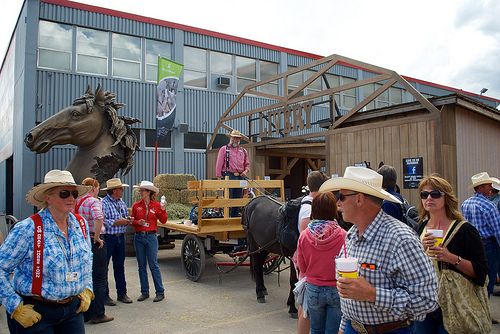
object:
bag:
[436, 219, 492, 334]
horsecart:
[126, 173, 309, 318]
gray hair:
[228, 137, 241, 147]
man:
[460, 171, 500, 299]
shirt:
[215, 142, 250, 176]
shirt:
[72, 193, 108, 234]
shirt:
[0, 207, 93, 315]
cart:
[131, 173, 285, 282]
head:
[335, 189, 381, 223]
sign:
[402, 156, 423, 189]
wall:
[323, 104, 499, 214]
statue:
[23, 81, 144, 197]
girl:
[291, 191, 349, 333]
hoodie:
[296, 219, 350, 288]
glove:
[75, 288, 94, 315]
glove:
[10, 301, 42, 328]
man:
[0, 169, 96, 333]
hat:
[225, 129, 245, 140]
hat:
[24, 169, 93, 208]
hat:
[132, 180, 159, 196]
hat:
[317, 165, 403, 205]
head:
[44, 185, 79, 211]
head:
[106, 186, 124, 199]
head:
[138, 188, 152, 200]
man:
[96, 178, 136, 309]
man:
[133, 179, 168, 302]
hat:
[465, 171, 498, 193]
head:
[473, 183, 493, 197]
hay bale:
[132, 174, 221, 221]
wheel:
[180, 233, 207, 282]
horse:
[240, 193, 309, 319]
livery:
[258, 100, 314, 139]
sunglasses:
[339, 192, 362, 202]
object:
[361, 263, 377, 270]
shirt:
[334, 207, 440, 327]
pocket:
[356, 265, 379, 285]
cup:
[335, 256, 359, 278]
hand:
[336, 274, 376, 303]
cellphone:
[360, 263, 376, 269]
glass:
[425, 229, 443, 259]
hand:
[427, 246, 448, 262]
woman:
[412, 171, 488, 333]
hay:
[130, 174, 223, 219]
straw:
[341, 236, 346, 258]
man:
[317, 165, 440, 333]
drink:
[334, 257, 360, 279]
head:
[23, 82, 142, 183]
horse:
[21, 81, 144, 199]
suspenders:
[142, 202, 150, 228]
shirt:
[131, 199, 169, 233]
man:
[214, 130, 250, 218]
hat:
[100, 178, 128, 191]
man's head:
[225, 130, 242, 148]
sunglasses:
[49, 188, 82, 201]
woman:
[127, 182, 169, 304]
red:
[149, 215, 156, 222]